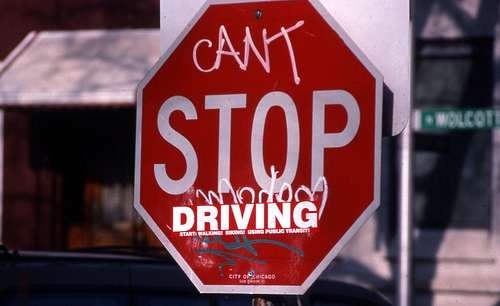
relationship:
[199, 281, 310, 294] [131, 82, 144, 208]
border on border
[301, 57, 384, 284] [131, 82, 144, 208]
border on border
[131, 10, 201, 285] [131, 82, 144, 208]
border on border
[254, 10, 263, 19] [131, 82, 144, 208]
bolt in border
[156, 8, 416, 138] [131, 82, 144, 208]
sign behind border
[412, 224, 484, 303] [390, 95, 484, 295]
structure behind street sign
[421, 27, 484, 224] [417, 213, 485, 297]
shadow on wall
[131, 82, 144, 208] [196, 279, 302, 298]
border with border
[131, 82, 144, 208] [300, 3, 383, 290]
border with border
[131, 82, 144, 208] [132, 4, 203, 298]
border with border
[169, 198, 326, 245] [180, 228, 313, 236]
bumper sticker encourages public transportation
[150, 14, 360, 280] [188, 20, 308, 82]
graffiti misspells contraction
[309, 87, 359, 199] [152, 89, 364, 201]
p in font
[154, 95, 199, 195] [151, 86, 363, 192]
letters in font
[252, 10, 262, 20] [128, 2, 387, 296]
bolt holds up poster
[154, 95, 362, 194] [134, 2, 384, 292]
letters in signal board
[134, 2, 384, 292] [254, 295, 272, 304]
signal board attached to pole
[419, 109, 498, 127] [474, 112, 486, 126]
background with letter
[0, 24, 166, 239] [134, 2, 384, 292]
building near signal board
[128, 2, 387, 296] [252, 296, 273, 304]
poster attached to pole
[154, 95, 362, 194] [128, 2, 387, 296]
letters on poster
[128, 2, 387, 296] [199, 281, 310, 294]
poster has border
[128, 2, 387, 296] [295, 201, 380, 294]
poster has side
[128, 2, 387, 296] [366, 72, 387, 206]
poster has side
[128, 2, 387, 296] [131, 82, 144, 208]
poster has border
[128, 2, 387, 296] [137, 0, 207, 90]
poster has side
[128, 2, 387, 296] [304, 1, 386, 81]
poster has side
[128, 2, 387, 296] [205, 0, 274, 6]
poster has border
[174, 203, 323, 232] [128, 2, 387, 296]
sticker stuck on poster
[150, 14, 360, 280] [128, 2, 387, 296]
graffiti on poster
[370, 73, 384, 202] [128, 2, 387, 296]
border on poster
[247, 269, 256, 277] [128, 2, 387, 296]
screw securing poster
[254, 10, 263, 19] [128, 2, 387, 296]
bolt securing poster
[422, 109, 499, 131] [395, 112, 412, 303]
background mounted on pole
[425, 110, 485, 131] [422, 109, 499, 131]
lettering painted on background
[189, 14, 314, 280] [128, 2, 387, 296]
graffiti on poster